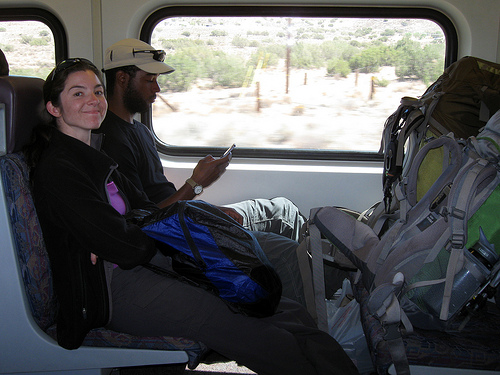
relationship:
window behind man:
[137, 2, 461, 164] [102, 35, 307, 296]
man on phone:
[102, 35, 307, 296] [216, 142, 239, 160]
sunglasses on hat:
[134, 46, 166, 64] [95, 37, 179, 75]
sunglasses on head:
[52, 57, 100, 82] [40, 57, 109, 131]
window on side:
[137, 2, 461, 164] [1, 0, 499, 209]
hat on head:
[95, 37, 179, 75] [101, 36, 175, 111]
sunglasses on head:
[134, 46, 166, 64] [101, 36, 175, 111]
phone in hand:
[216, 142, 239, 160] [185, 141, 236, 194]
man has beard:
[102, 35, 307, 296] [120, 81, 153, 114]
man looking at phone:
[102, 35, 307, 296] [216, 142, 239, 160]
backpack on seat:
[302, 107, 500, 342] [354, 279, 499, 373]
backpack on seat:
[384, 53, 497, 217] [354, 279, 499, 373]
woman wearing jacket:
[28, 57, 361, 374] [33, 135, 158, 349]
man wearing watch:
[102, 35, 307, 296] [184, 178, 204, 195]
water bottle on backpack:
[423, 227, 500, 322] [302, 107, 500, 342]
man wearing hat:
[102, 35, 307, 296] [95, 37, 179, 75]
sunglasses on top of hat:
[134, 46, 166, 64] [95, 37, 179, 75]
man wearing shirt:
[102, 35, 307, 296] [98, 111, 182, 207]